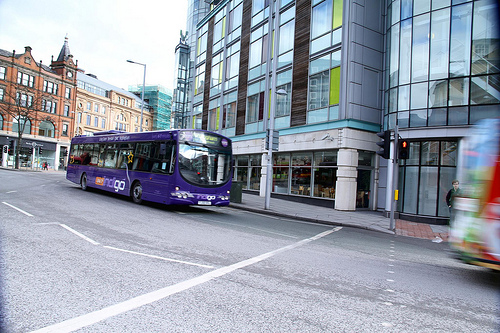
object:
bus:
[65, 129, 235, 206]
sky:
[0, 0, 185, 98]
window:
[204, 49, 223, 84]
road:
[0, 162, 499, 331]